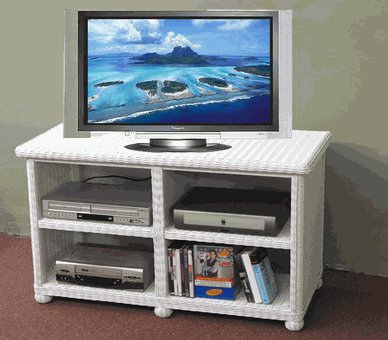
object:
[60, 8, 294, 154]
television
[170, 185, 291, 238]
media box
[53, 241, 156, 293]
vcr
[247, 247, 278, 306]
collection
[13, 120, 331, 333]
stand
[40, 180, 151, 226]
dvd/vcr combo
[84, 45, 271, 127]
islands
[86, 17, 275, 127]
screen